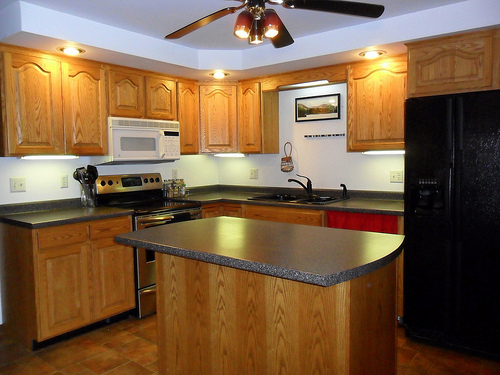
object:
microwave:
[95, 116, 182, 166]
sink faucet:
[247, 173, 350, 205]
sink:
[248, 195, 348, 205]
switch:
[9, 176, 27, 192]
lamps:
[58, 43, 85, 57]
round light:
[209, 69, 230, 80]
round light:
[359, 49, 385, 59]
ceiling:
[1, 0, 498, 80]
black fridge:
[401, 89, 499, 357]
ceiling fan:
[163, 1, 384, 49]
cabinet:
[108, 69, 176, 121]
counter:
[111, 214, 408, 375]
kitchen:
[0, 0, 500, 375]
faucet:
[288, 173, 313, 197]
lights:
[233, 10, 280, 45]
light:
[233, 23, 280, 45]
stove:
[73, 164, 166, 206]